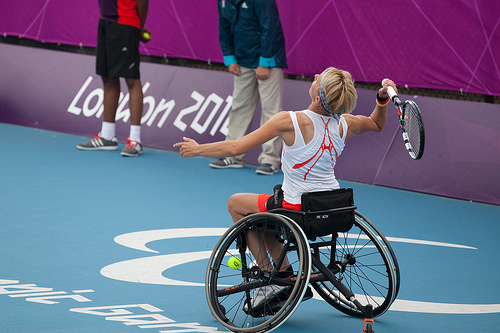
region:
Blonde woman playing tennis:
[165, 64, 442, 331]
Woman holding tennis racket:
[171, 64, 464, 324]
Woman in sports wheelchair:
[145, 56, 420, 325]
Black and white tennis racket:
[374, 71, 436, 167]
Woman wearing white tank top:
[177, 57, 448, 242]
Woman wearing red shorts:
[165, 59, 399, 331]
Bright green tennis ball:
[220, 254, 245, 276]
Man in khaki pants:
[203, 2, 292, 176]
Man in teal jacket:
[202, 2, 309, 174]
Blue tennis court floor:
[6, 136, 488, 322]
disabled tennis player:
[12, 10, 468, 305]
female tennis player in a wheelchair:
[155, 47, 454, 323]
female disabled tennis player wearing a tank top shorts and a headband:
[156, 58, 430, 328]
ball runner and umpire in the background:
[64, 2, 295, 182]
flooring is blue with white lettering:
[22, 101, 497, 328]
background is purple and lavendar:
[5, 3, 495, 198]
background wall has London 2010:
[55, 42, 440, 198]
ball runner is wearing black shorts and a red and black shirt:
[77, 0, 155, 172]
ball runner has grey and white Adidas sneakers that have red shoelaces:
[71, 109, 146, 174]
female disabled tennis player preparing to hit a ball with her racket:
[137, 59, 454, 327]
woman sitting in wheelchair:
[168, 65, 401, 332]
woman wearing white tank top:
[275, 107, 347, 204]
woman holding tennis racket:
[378, 75, 427, 161]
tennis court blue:
[0, 122, 496, 331]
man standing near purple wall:
[208, 0, 288, 177]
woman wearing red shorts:
[256, 193, 303, 215]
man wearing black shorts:
[93, 17, 143, 79]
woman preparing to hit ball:
[171, 63, 397, 313]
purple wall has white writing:
[65, 75, 237, 139]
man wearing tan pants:
[223, 65, 283, 168]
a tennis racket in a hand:
[371, 72, 442, 167]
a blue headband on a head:
[314, 64, 340, 119]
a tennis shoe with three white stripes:
[69, 125, 123, 154]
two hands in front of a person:
[212, 46, 291, 93]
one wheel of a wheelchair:
[198, 206, 318, 330]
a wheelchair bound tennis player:
[163, 56, 443, 329]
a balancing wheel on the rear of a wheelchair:
[346, 290, 383, 330]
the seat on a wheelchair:
[263, 183, 364, 238]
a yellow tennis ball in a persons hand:
[135, 21, 157, 51]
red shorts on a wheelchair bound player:
[248, 180, 311, 225]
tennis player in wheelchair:
[168, 65, 426, 330]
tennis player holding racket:
[371, 68, 428, 163]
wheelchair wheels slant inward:
[204, 209, 400, 331]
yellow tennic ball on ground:
[228, 254, 240, 271]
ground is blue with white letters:
[0, 119, 497, 331]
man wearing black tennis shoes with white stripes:
[73, 132, 143, 155]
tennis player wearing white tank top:
[276, 106, 344, 208]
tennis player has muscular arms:
[138, 79, 400, 161]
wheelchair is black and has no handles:
[196, 186, 407, 328]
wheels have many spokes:
[201, 211, 403, 331]